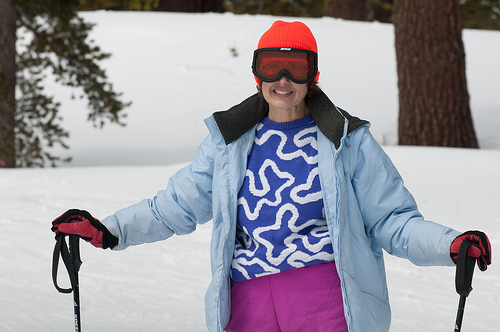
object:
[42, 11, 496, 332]
woman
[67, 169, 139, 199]
snow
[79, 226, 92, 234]
pink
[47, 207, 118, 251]
glove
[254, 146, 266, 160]
purple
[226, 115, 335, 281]
shirt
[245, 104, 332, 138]
top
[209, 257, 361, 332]
pants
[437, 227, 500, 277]
hand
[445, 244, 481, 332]
pole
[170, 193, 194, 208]
blue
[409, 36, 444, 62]
brown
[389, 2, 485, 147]
trunk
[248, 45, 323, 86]
goggles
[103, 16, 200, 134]
ground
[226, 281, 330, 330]
these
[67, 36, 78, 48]
these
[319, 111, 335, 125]
black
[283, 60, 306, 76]
eye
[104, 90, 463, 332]
coat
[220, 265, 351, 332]
pair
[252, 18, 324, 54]
orange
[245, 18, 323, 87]
cap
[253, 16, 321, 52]
hat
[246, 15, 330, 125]
head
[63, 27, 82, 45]
leaf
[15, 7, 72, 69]
limb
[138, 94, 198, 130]
snowy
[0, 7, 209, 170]
slope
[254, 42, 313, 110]
face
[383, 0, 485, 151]
tree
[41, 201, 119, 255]
hand